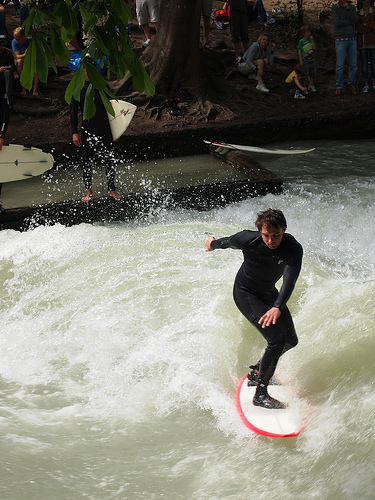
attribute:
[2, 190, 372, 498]
wave — choppy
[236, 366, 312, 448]
surfboard — white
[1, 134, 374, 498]
water — white, splashes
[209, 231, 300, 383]
wet suit — black, in photo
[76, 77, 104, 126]
leaf — green, hanging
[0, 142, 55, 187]
surfboard — white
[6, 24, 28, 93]
person — in background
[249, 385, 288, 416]
shoe — in photo, black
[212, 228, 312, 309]
rashguard — black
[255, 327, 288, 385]
legging — black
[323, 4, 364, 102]
spectator — in background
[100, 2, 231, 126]
trunk — large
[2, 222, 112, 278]
foam — white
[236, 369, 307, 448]
edge — red